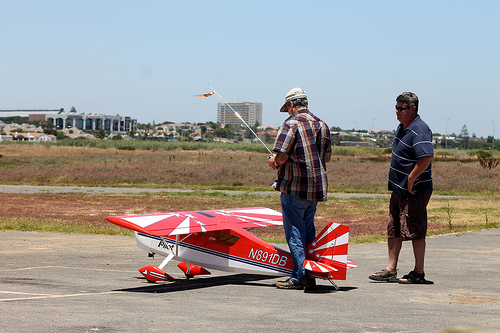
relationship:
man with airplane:
[266, 86, 332, 291] [98, 202, 344, 300]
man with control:
[266, 86, 332, 291] [219, 111, 330, 203]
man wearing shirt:
[367, 91, 438, 284] [392, 125, 433, 187]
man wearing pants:
[367, 91, 438, 284] [390, 184, 427, 234]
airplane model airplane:
[103, 204, 360, 287] [103, 204, 360, 287]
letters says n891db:
[242, 244, 294, 263] [253, 254, 276, 260]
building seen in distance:
[211, 101, 266, 136] [146, 101, 275, 158]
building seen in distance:
[23, 111, 142, 133] [24, 144, 148, 234]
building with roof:
[3, 96, 61, 183] [17, 134, 67, 140]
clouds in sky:
[25, 51, 61, 86] [52, 99, 154, 102]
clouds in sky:
[332, 104, 370, 119] [13, 55, 498, 110]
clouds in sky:
[92, 59, 129, 93] [164, 100, 231, 107]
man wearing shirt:
[266, 86, 332, 291] [284, 111, 322, 183]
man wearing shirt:
[368, 102, 450, 315] [392, 159, 434, 179]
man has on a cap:
[266, 86, 332, 291] [275, 100, 312, 110]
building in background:
[211, 101, 263, 131] [138, 100, 246, 160]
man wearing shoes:
[367, 91, 438, 284] [362, 263, 438, 283]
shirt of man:
[392, 126, 430, 195] [384, 112, 436, 282]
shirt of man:
[272, 135, 312, 181] [268, 76, 336, 284]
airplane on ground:
[99, 196, 357, 298] [42, 169, 392, 333]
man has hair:
[367, 91, 438, 284] [394, 99, 418, 109]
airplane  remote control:
[103, 204, 360, 287] [248, 136, 278, 176]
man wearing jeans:
[266, 86, 332, 291] [288, 194, 319, 276]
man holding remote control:
[277, 93, 327, 291] [256, 142, 276, 176]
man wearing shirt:
[266, 86, 332, 291] [294, 120, 329, 183]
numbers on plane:
[247, 248, 295, 268] [118, 192, 351, 313]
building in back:
[23, 111, 142, 133] [47, 102, 157, 137]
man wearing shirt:
[367, 91, 438, 284] [386, 116, 430, 197]